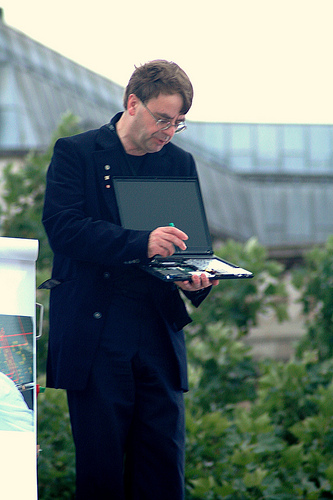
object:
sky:
[0, 0, 333, 128]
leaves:
[249, 247, 259, 265]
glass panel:
[229, 122, 253, 174]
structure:
[0, 19, 333, 263]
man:
[42, 56, 222, 500]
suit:
[39, 109, 214, 500]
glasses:
[134, 95, 186, 135]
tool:
[168, 222, 181, 258]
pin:
[102, 162, 113, 172]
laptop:
[110, 175, 255, 283]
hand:
[173, 273, 209, 295]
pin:
[90, 310, 102, 322]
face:
[132, 93, 185, 153]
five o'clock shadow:
[128, 110, 172, 155]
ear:
[126, 91, 137, 119]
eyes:
[155, 115, 170, 130]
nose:
[164, 118, 177, 138]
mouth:
[150, 134, 168, 146]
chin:
[142, 143, 163, 157]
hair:
[121, 57, 194, 121]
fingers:
[161, 225, 188, 240]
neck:
[115, 111, 148, 159]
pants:
[63, 285, 189, 498]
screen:
[115, 182, 211, 253]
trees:
[0, 106, 333, 499]